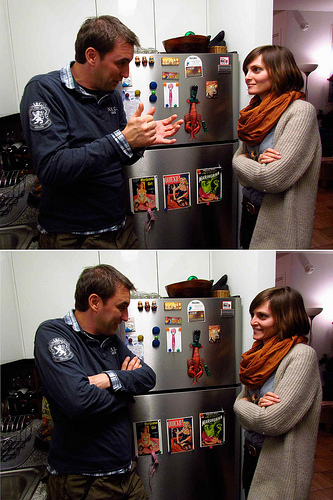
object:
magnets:
[132, 54, 232, 136]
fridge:
[120, 50, 244, 248]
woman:
[230, 43, 320, 244]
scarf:
[233, 90, 305, 141]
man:
[22, 12, 180, 248]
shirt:
[21, 63, 129, 230]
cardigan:
[240, 97, 320, 247]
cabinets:
[3, 1, 97, 119]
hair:
[240, 47, 303, 92]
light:
[301, 60, 319, 101]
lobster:
[183, 82, 205, 141]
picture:
[161, 68, 178, 107]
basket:
[163, 34, 212, 52]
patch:
[27, 101, 52, 130]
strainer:
[0, 172, 28, 211]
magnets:
[134, 57, 157, 64]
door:
[111, 54, 237, 138]